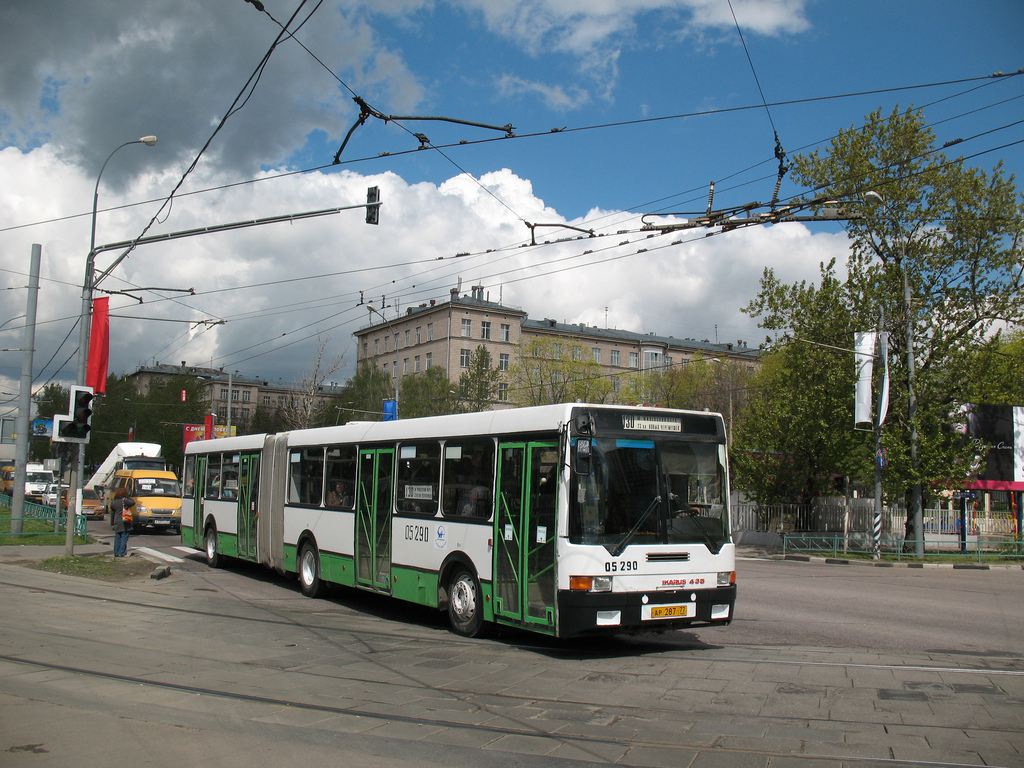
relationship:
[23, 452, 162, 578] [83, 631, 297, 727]
car on pavement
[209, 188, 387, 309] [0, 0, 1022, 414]
clouds are in clouds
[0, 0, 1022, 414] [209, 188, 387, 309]
clouds has clouds